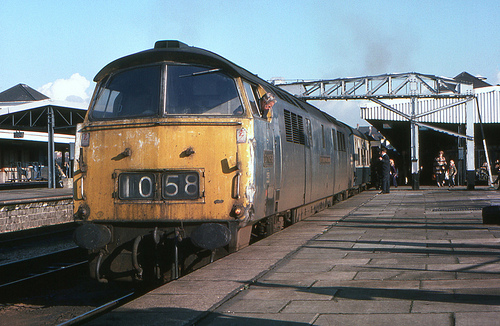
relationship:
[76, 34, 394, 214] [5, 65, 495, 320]
train at a station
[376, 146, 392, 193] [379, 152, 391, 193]
man in suit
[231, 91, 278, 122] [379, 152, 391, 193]
man in suit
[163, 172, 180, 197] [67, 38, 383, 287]
number on train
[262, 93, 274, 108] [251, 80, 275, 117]
head out window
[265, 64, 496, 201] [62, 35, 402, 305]
structure over train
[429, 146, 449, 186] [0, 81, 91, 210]
woman at station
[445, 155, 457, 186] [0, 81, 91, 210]
child at station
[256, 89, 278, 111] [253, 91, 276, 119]
head on man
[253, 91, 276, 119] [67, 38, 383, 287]
man on train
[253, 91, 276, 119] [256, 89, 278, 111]
man sticking out h head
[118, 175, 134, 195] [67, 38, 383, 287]
number on train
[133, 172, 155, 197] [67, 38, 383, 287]
number on train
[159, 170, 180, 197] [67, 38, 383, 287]
number on train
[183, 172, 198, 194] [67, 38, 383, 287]
number on train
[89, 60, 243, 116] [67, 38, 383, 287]
windshields on train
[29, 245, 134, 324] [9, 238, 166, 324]
train tracks on ground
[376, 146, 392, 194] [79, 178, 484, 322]
man standing on platform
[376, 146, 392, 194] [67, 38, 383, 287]
man standing next to train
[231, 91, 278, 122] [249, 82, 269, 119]
man leaning out of window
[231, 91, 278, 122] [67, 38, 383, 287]
man leaning out of train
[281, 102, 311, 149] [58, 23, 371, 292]
grate mounted on train